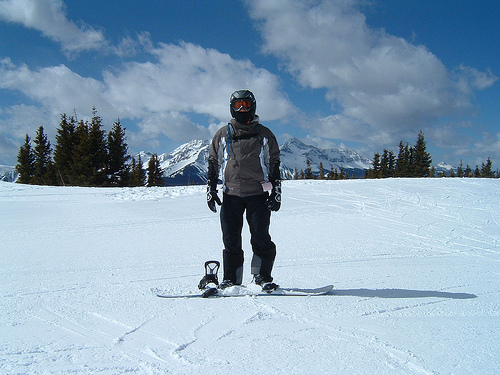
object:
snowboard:
[150, 282, 335, 298]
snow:
[2, 179, 499, 371]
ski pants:
[220, 190, 277, 285]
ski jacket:
[207, 117, 281, 197]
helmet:
[229, 89, 256, 124]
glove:
[206, 179, 222, 213]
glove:
[264, 178, 281, 212]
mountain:
[122, 134, 419, 185]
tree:
[386, 128, 431, 180]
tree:
[32, 124, 54, 185]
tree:
[54, 112, 75, 188]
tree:
[144, 154, 164, 187]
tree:
[105, 119, 130, 185]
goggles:
[229, 98, 256, 112]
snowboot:
[218, 276, 243, 289]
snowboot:
[250, 271, 279, 294]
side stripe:
[216, 136, 228, 203]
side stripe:
[259, 136, 274, 195]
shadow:
[277, 284, 478, 299]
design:
[205, 179, 212, 202]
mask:
[230, 105, 257, 124]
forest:
[15, 104, 500, 188]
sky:
[2, 3, 498, 166]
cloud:
[73, 89, 179, 129]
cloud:
[265, 3, 383, 119]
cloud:
[299, 109, 375, 146]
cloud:
[0, 2, 103, 52]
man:
[207, 89, 282, 293]